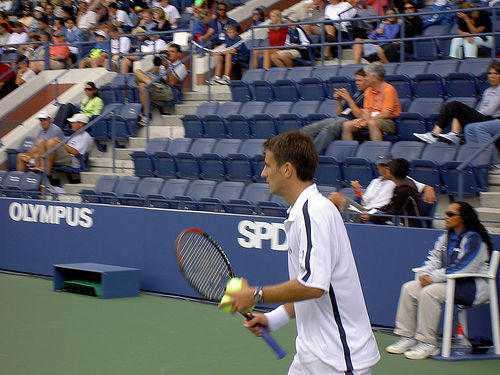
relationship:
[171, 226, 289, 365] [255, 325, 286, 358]
racket has handle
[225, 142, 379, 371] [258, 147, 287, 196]
guy has face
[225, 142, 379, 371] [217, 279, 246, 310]
player holding balls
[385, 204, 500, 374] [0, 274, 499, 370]
official on court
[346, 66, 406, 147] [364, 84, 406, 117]
spectator has shirt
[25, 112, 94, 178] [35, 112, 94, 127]
men in hats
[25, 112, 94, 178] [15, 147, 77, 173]
men in shorts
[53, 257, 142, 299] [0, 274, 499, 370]
stand on court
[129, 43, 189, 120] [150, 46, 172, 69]
man has camera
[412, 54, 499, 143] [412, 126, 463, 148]
person has feet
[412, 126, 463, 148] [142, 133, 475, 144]
feet on row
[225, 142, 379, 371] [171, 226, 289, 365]
man holds racket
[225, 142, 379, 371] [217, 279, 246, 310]
man holds balls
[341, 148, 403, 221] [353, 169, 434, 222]
man wearing shirt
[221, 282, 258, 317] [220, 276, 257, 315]
hand has balls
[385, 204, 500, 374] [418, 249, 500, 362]
lady in chair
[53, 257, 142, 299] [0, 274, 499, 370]
stool on court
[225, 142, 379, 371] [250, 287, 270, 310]
man has watch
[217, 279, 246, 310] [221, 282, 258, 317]
balls in hand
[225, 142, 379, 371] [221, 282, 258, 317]
man has hand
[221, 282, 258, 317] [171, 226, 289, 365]
hand has racket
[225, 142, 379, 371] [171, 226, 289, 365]
player has racket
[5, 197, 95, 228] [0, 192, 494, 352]
olympus on wall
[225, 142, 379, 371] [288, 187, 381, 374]
player has shirt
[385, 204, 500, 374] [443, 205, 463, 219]
woman wears sunglasses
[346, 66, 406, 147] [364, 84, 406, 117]
fan has shirt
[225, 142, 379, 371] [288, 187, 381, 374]
player wears white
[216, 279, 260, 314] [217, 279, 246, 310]
hand holding balls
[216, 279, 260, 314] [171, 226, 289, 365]
hand holding racket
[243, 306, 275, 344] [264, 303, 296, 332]
hand has band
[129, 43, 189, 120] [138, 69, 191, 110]
man in chair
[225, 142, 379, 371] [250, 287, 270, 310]
player has watch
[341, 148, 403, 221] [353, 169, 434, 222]
man wears shirt